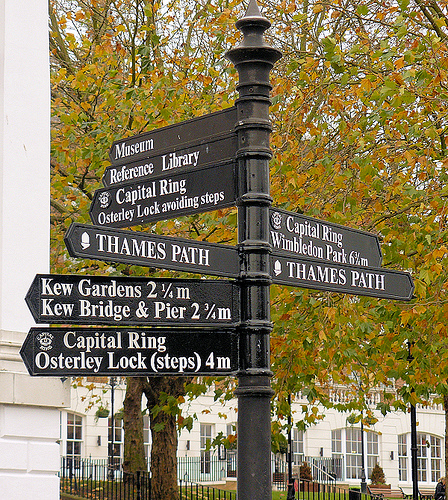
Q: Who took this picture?
A: A person on the street.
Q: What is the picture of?
A: The picture is of a street sign.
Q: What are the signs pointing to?
A: Thames Path and the Capital Ring.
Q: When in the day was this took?
A: During the daylight hours.